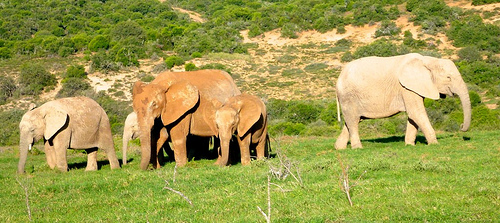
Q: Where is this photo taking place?
A: A field.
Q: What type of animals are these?
A: Elephants.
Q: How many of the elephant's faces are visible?
A: Five.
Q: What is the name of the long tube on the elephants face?
A: Trunk.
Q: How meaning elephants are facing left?
A: Four.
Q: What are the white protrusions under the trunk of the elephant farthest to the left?
A: Tusks.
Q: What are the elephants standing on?
A: Grass.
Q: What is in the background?
A: A hill.